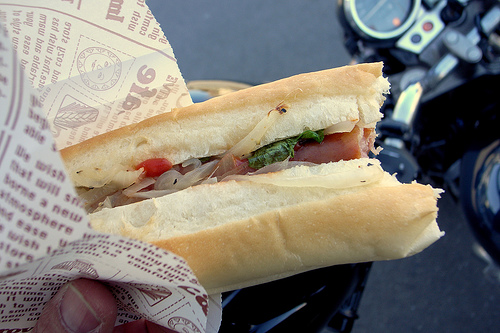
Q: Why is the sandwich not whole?
A: It's been bitten.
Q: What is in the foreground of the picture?
A: A sandwich.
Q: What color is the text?
A: Red.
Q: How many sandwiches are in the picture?
A: One.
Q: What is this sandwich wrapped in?
A: Paper.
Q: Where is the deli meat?
A: The sandwich.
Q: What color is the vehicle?
A: Black.